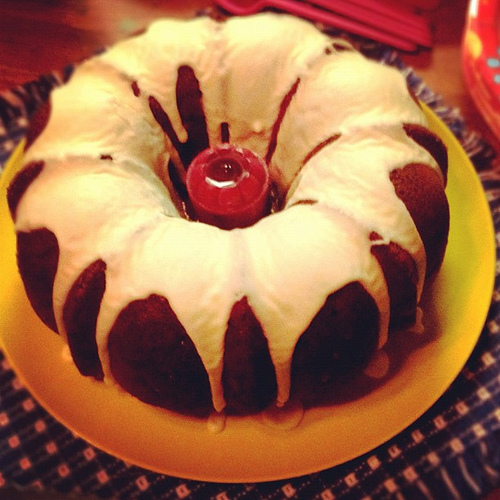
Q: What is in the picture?
A: A cake.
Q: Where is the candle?
A: Middle of the cake.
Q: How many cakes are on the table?
A: One.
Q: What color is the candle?
A: Red.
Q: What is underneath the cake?
A: A plate.